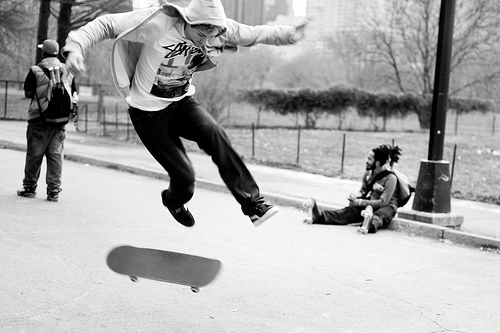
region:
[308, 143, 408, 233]
Man sitting on sidewalk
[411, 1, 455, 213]
Black pole on sidewalk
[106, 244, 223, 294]
Skateboard in midair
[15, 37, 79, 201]
Man wearing baseball cap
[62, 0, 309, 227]
Man doing a trick on skateboard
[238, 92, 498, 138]
Trees behind a skateboarder doing a trick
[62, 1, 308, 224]
Man wearing dark pants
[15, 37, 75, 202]
Man wearing backpack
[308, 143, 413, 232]
Man with a ponytail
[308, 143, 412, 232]
Man wearing skates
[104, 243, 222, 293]
A skateboard in the air.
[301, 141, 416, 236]
A man sitting down.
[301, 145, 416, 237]
A man wearing roller skates.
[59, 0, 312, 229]
A man in the air.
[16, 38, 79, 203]
A man with a backpack.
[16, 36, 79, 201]
A man on the street.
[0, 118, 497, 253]
A man sitting on a sidewalk.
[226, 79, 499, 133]
Vines on a fence.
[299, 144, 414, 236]
A man with a ponytail.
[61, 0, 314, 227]
A man doing tricks.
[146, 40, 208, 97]
print on the front of a skater's shirt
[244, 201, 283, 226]
dark colored shoe on a skater's foot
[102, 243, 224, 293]
skateboard on the air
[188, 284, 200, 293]
wheel of a skateboard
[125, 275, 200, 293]
two wheels on a skateboard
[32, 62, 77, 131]
dark colored backpack on the man's back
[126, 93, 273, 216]
dark colored pants on a skater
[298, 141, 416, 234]
man sitting down on the curb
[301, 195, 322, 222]
skates on a man's foot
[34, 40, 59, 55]
hat on a man's head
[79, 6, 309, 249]
a boy jumping in the air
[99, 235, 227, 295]
a skateboard in midair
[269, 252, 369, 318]
grey concrete surface of the road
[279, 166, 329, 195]
grey concrete surface of the sidewalk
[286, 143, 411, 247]
a man sitting on the sidewalk wearing roller skates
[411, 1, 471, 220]
a black street post on the sidewalk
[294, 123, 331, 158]
grey grass of the park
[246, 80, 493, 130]
plants growing over the top of the fence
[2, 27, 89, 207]
a man wearing a backpack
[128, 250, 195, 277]
black surface of the skateboard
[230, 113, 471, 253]
a man sitting at the sidewalk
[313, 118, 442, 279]
a man sitting at the sidewalk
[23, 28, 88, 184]
the man is walking away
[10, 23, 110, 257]
the man is walking away